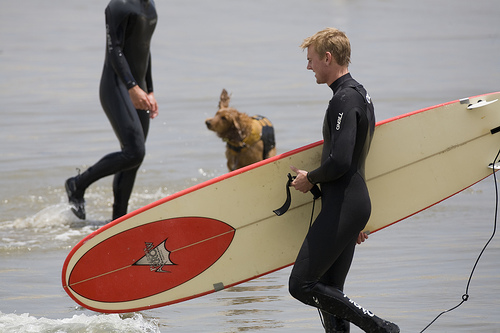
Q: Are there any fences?
A: No, there are no fences.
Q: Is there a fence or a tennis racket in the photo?
A: No, there are no fences or rackets.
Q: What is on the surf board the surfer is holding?
A: The logo is on the surfboard.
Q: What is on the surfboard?
A: The logo is on the surfboard.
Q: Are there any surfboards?
A: Yes, there is a surfboard.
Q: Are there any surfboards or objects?
A: Yes, there is a surfboard.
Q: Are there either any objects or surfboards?
A: Yes, there is a surfboard.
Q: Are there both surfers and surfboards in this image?
A: Yes, there are both a surfboard and a surfer.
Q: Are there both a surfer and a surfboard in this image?
A: Yes, there are both a surfboard and a surfer.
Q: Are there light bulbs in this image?
A: No, there are no light bulbs.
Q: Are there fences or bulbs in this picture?
A: No, there are no bulbs or fences.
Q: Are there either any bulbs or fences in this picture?
A: No, there are no bulbs or fences.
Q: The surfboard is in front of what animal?
A: The surfboard is in front of the dog.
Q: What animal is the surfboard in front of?
A: The surfboard is in front of the dog.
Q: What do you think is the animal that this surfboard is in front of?
A: The animal is a dog.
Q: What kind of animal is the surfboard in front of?
A: The surfboard is in front of the dog.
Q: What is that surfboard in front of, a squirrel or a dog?
A: The surfboard is in front of a dog.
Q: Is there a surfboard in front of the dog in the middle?
A: Yes, there is a surfboard in front of the dog.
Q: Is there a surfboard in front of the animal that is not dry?
A: Yes, there is a surfboard in front of the dog.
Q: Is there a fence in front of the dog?
A: No, there is a surfboard in front of the dog.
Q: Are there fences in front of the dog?
A: No, there is a surfboard in front of the dog.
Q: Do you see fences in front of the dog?
A: No, there is a surfboard in front of the dog.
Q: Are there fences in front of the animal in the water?
A: No, there is a surfboard in front of the dog.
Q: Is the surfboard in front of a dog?
A: Yes, the surfboard is in front of a dog.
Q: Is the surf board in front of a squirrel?
A: No, the surf board is in front of a dog.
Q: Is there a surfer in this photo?
A: Yes, there is a surfer.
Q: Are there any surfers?
A: Yes, there is a surfer.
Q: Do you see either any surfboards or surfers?
A: Yes, there is a surfer.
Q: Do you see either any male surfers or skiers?
A: Yes, there is a male surfer.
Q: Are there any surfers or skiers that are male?
A: Yes, the surfer is male.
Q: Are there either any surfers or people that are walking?
A: Yes, the surfer is walking.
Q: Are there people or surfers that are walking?
A: Yes, the surfer is walking.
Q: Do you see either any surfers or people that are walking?
A: Yes, the surfer is walking.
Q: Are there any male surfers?
A: Yes, there is a male surfer.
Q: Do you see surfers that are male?
A: Yes, there is a surfer that is male.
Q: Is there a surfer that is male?
A: Yes, there is a surfer that is male.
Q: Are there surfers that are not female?
A: Yes, there is a male surfer.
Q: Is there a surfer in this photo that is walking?
A: Yes, there is a surfer that is walking.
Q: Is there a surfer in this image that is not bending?
A: Yes, there is a surfer that is walking.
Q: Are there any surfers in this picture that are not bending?
A: Yes, there is a surfer that is walking.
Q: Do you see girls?
A: No, there are no girls.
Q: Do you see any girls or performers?
A: No, there are no girls or performers.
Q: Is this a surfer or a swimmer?
A: This is a surfer.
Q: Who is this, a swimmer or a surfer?
A: This is a surfer.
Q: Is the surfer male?
A: Yes, the surfer is male.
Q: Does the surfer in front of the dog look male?
A: Yes, the surfer is male.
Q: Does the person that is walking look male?
A: Yes, the surfer is male.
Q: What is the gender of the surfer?
A: The surfer is male.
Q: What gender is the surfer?
A: The surfer is male.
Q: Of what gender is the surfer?
A: The surfer is male.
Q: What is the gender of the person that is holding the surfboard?
A: The surfer is male.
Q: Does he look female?
A: No, the surfer is male.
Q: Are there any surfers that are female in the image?
A: No, there is a surfer but he is male.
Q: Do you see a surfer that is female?
A: No, there is a surfer but he is male.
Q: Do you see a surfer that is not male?
A: No, there is a surfer but he is male.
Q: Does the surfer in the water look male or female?
A: The surfer is male.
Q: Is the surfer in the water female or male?
A: The surfer is male.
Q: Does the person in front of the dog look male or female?
A: The surfer is male.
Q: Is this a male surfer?
A: Yes, this is a male surfer.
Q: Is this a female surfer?
A: No, this is a male surfer.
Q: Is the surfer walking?
A: Yes, the surfer is walking.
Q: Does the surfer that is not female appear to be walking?
A: Yes, the surfer is walking.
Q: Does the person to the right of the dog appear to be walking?
A: Yes, the surfer is walking.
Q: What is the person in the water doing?
A: The surfer is walking.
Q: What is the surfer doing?
A: The surfer is walking.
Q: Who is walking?
A: The surfer is walking.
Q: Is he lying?
A: No, the surfer is walking.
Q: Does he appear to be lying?
A: No, the surfer is walking.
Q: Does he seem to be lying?
A: No, the surfer is walking.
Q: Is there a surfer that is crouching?
A: No, there is a surfer but he is walking.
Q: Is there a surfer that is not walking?
A: No, there is a surfer but he is walking.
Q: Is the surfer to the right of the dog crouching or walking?
A: The surfer is walking.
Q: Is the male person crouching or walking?
A: The surfer is walking.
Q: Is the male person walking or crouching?
A: The surfer is walking.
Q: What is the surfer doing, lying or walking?
A: The surfer is walking.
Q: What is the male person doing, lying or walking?
A: The surfer is walking.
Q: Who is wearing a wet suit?
A: The surfer is wearing a wet suit.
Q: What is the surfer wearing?
A: The surfer is wearing a wet suit.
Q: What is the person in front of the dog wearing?
A: The surfer is wearing a wet suit.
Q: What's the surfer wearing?
A: The surfer is wearing a wet suit.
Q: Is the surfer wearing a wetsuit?
A: Yes, the surfer is wearing a wetsuit.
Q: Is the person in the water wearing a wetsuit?
A: Yes, the surfer is wearing a wetsuit.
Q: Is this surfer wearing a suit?
A: No, the surfer is wearing a wetsuit.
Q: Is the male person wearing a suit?
A: No, the surfer is wearing a wetsuit.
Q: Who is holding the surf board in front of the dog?
A: The surfer is holding the surfboard.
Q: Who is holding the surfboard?
A: The surfer is holding the surfboard.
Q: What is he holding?
A: The surfer is holding the surfboard.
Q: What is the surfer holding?
A: The surfer is holding the surfboard.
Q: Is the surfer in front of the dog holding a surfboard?
A: Yes, the surfer is holding a surfboard.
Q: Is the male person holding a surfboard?
A: Yes, the surfer is holding a surfboard.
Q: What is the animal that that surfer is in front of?
A: The animal is a dog.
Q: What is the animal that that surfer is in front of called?
A: The animal is a dog.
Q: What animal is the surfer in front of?
A: The surfer is in front of the dog.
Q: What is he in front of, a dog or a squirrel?
A: The surfer is in front of a dog.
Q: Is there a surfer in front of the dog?
A: Yes, there is a surfer in front of the dog.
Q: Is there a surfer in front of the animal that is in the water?
A: Yes, there is a surfer in front of the dog.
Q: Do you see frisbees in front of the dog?
A: No, there is a surfer in front of the dog.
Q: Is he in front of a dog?
A: Yes, the surfer is in front of a dog.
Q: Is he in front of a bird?
A: No, the surfer is in front of a dog.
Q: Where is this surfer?
A: The surfer is in the water.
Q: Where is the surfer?
A: The surfer is in the water.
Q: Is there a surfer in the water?
A: Yes, there is a surfer in the water.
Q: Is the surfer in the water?
A: Yes, the surfer is in the water.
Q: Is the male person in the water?
A: Yes, the surfer is in the water.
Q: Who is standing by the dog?
A: The surfer is standing by the dog.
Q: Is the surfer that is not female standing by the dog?
A: Yes, the surfer is standing by the dog.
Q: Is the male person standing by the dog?
A: Yes, the surfer is standing by the dog.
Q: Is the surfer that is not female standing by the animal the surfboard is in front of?
A: Yes, the surfer is standing by the dog.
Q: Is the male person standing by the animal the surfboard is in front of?
A: Yes, the surfer is standing by the dog.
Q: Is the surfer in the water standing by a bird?
A: No, the surfer is standing by the dog.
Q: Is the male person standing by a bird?
A: No, the surfer is standing by the dog.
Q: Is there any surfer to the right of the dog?
A: Yes, there is a surfer to the right of the dog.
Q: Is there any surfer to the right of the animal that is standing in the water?
A: Yes, there is a surfer to the right of the dog.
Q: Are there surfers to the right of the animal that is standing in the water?
A: Yes, there is a surfer to the right of the dog.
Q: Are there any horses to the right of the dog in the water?
A: No, there is a surfer to the right of the dog.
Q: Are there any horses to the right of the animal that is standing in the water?
A: No, there is a surfer to the right of the dog.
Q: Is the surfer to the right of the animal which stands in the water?
A: Yes, the surfer is to the right of the dog.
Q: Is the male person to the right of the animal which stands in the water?
A: Yes, the surfer is to the right of the dog.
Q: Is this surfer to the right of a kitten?
A: No, the surfer is to the right of the dog.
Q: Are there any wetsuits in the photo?
A: Yes, there is a wetsuit.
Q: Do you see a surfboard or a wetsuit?
A: Yes, there is a wetsuit.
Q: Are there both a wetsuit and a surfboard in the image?
A: Yes, there are both a wetsuit and a surfboard.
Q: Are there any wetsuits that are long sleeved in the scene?
A: Yes, there is a long sleeved wetsuit.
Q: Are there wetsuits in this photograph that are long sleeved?
A: Yes, there is a wetsuit that is long sleeved.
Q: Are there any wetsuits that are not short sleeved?
A: Yes, there is a long sleeved wetsuit.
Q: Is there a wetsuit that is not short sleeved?
A: Yes, there is a long sleeved wetsuit.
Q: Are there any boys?
A: No, there are no boys.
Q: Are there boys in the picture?
A: No, there are no boys.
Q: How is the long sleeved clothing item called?
A: The clothing item is a wetsuit.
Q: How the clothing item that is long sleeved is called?
A: The clothing item is a wetsuit.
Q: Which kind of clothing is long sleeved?
A: The clothing is a wetsuit.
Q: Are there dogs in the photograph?
A: Yes, there is a dog.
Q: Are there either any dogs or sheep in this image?
A: Yes, there is a dog.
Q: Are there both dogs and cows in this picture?
A: No, there is a dog but no cows.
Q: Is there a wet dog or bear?
A: Yes, there is a wet dog.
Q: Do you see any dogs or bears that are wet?
A: Yes, the dog is wet.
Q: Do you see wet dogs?
A: Yes, there is a wet dog.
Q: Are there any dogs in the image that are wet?
A: Yes, there is a dog that is wet.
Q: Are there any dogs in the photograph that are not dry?
A: Yes, there is a wet dog.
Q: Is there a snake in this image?
A: No, there are no snakes.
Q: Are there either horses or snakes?
A: No, there are no snakes or horses.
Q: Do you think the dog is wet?
A: Yes, the dog is wet.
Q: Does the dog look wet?
A: Yes, the dog is wet.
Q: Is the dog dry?
A: No, the dog is wet.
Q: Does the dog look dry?
A: No, the dog is wet.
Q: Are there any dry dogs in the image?
A: No, there is a dog but it is wet.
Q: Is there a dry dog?
A: No, there is a dog but it is wet.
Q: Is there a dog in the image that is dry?
A: No, there is a dog but it is wet.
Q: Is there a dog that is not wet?
A: No, there is a dog but it is wet.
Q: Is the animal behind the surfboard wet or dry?
A: The dog is wet.